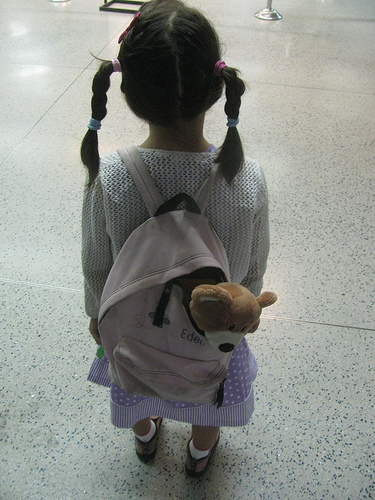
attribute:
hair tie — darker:
[214, 58, 227, 78]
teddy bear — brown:
[181, 282, 283, 350]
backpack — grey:
[99, 143, 268, 424]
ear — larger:
[190, 283, 231, 303]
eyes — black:
[229, 322, 252, 332]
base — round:
[254, 7, 281, 20]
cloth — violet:
[119, 352, 277, 418]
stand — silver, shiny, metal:
[249, 1, 325, 32]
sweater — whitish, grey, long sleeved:
[81, 146, 269, 319]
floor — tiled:
[292, 39, 345, 175]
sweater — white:
[72, 165, 281, 379]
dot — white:
[232, 372, 240, 380]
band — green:
[87, 117, 101, 132]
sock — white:
[189, 439, 212, 458]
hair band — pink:
[207, 53, 230, 75]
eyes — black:
[224, 314, 254, 340]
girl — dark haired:
[77, 2, 282, 478]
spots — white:
[229, 357, 246, 403]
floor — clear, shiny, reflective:
[0, 1, 363, 490]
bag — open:
[87, 202, 246, 405]